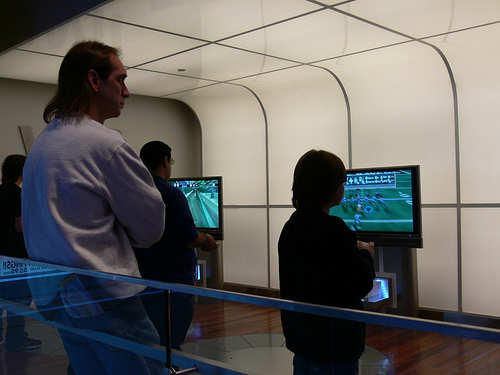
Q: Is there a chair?
A: No, there are no chairs.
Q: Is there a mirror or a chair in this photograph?
A: No, there are no chairs or mirrors.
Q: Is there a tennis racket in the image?
A: No, there are no rackets.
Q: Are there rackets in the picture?
A: No, there are no rackets.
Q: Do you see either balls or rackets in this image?
A: No, there are no rackets or balls.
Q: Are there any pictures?
A: No, there are no pictures.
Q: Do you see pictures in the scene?
A: No, there are no pictures.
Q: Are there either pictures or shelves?
A: No, there are no pictures or shelves.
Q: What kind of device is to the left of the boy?
A: The device is a screen.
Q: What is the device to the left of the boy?
A: The device is a screen.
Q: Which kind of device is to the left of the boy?
A: The device is a screen.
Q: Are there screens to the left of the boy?
A: Yes, there is a screen to the left of the boy.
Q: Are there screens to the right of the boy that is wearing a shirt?
A: No, the screen is to the left of the boy.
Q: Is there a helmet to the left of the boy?
A: No, there is a screen to the left of the boy.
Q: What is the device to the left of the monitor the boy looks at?
A: The device is a screen.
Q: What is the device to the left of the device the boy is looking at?
A: The device is a screen.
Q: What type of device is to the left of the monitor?
A: The device is a screen.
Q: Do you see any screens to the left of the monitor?
A: Yes, there is a screen to the left of the monitor.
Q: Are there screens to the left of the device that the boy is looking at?
A: Yes, there is a screen to the left of the monitor.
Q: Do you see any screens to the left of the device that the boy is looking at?
A: Yes, there is a screen to the left of the monitor.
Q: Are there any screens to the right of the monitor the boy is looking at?
A: No, the screen is to the left of the monitor.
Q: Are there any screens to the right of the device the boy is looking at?
A: No, the screen is to the left of the monitor.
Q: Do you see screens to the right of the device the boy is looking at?
A: No, the screen is to the left of the monitor.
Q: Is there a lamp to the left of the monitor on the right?
A: No, there is a screen to the left of the monitor.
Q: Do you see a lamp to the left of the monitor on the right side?
A: No, there is a screen to the left of the monitor.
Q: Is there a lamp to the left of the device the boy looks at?
A: No, there is a screen to the left of the monitor.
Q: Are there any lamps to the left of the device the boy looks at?
A: No, there is a screen to the left of the monitor.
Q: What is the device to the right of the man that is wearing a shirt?
A: The device is a screen.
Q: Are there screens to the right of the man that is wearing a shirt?
A: Yes, there is a screen to the right of the man.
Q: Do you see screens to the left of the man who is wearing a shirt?
A: No, the screen is to the right of the man.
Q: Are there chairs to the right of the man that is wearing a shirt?
A: No, there is a screen to the right of the man.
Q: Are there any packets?
A: No, there are no packets.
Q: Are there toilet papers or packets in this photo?
A: No, there are no packets or toilet papers.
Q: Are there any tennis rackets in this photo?
A: No, there are no tennis rackets.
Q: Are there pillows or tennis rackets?
A: No, there are no tennis rackets or pillows.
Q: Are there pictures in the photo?
A: No, there are no pictures.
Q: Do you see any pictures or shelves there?
A: No, there are no pictures or shelves.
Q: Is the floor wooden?
A: Yes, the floor is wooden.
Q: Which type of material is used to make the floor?
A: The floor is made of wood.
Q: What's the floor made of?
A: The floor is made of wood.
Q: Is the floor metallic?
A: No, the floor is wooden.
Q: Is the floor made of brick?
A: No, the floor is made of wood.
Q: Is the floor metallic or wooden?
A: The floor is wooden.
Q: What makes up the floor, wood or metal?
A: The floor is made of wood.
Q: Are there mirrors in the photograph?
A: No, there are no mirrors.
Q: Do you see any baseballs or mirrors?
A: No, there are no mirrors or baseballs.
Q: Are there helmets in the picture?
A: No, there are no helmets.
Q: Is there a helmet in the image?
A: No, there are no helmets.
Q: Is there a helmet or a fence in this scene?
A: No, there are no helmets or fences.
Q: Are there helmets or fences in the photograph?
A: No, there are no helmets or fences.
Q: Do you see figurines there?
A: No, there are no figurines.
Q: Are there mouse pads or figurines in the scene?
A: No, there are no figurines or mouse pads.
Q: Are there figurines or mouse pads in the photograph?
A: No, there are no figurines or mouse pads.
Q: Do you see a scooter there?
A: No, there are no scooters.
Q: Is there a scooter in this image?
A: No, there are no scooters.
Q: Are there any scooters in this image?
A: No, there are no scooters.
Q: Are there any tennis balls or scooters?
A: No, there are no scooters or tennis balls.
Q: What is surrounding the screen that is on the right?
A: The frame is surrounding the screen.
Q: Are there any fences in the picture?
A: No, there are no fences.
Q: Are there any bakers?
A: No, there are no bakers.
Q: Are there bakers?
A: No, there are no bakers.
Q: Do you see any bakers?
A: No, there are no bakers.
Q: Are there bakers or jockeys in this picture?
A: No, there are no bakers or jockeys.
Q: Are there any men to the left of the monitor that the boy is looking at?
A: Yes, there is a man to the left of the monitor.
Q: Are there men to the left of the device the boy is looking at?
A: Yes, there is a man to the left of the monitor.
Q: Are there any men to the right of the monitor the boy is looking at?
A: No, the man is to the left of the monitor.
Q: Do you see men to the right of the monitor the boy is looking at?
A: No, the man is to the left of the monitor.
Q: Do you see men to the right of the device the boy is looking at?
A: No, the man is to the left of the monitor.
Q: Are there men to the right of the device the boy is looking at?
A: No, the man is to the left of the monitor.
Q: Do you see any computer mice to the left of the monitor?
A: No, there is a man to the left of the monitor.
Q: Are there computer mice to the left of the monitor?
A: No, there is a man to the left of the monitor.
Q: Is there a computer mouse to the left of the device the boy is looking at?
A: No, there is a man to the left of the monitor.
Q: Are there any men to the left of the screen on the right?
A: Yes, there is a man to the left of the screen.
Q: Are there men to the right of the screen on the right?
A: No, the man is to the left of the screen.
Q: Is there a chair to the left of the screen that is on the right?
A: No, there is a man to the left of the screen.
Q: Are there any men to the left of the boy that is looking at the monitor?
A: Yes, there is a man to the left of the boy.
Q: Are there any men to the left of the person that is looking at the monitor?
A: Yes, there is a man to the left of the boy.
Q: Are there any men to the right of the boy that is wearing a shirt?
A: No, the man is to the left of the boy.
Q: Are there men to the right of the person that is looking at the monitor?
A: No, the man is to the left of the boy.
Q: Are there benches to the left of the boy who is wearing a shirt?
A: No, there is a man to the left of the boy.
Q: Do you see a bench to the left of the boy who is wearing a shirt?
A: No, there is a man to the left of the boy.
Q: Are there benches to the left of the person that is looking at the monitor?
A: No, there is a man to the left of the boy.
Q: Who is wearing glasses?
A: The man is wearing glasses.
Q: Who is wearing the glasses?
A: The man is wearing glasses.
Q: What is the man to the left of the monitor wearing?
A: The man is wearing glasses.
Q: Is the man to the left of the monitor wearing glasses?
A: Yes, the man is wearing glasses.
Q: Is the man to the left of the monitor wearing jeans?
A: No, the man is wearing glasses.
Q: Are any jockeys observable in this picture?
A: No, there are no jockeys.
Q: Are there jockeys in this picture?
A: No, there are no jockeys.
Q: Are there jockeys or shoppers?
A: No, there are no jockeys or shoppers.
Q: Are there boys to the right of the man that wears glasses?
A: Yes, there is a boy to the right of the man.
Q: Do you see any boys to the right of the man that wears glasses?
A: Yes, there is a boy to the right of the man.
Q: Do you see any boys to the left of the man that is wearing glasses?
A: No, the boy is to the right of the man.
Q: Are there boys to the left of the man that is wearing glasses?
A: No, the boy is to the right of the man.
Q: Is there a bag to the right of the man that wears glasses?
A: No, there is a boy to the right of the man.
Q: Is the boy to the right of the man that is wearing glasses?
A: Yes, the boy is to the right of the man.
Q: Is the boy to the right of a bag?
A: No, the boy is to the right of the man.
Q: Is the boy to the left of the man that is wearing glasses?
A: No, the boy is to the right of the man.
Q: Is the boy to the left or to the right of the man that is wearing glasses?
A: The boy is to the right of the man.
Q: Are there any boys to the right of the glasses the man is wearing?
A: Yes, there is a boy to the right of the glasses.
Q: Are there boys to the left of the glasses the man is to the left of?
A: No, the boy is to the right of the glasses.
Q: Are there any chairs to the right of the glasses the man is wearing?
A: No, there is a boy to the right of the glasses.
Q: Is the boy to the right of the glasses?
A: Yes, the boy is to the right of the glasses.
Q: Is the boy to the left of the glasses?
A: No, the boy is to the right of the glasses.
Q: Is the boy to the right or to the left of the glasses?
A: The boy is to the right of the glasses.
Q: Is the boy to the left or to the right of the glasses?
A: The boy is to the right of the glasses.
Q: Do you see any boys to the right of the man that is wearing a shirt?
A: Yes, there is a boy to the right of the man.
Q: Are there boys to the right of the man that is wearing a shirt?
A: Yes, there is a boy to the right of the man.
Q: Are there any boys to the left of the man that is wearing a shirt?
A: No, the boy is to the right of the man.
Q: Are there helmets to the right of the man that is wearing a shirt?
A: No, there is a boy to the right of the man.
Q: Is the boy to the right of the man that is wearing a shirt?
A: Yes, the boy is to the right of the man.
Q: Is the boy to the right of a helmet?
A: No, the boy is to the right of the man.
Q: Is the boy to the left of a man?
A: No, the boy is to the right of a man.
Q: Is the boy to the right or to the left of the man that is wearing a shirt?
A: The boy is to the right of the man.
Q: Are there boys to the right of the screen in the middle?
A: Yes, there is a boy to the right of the screen.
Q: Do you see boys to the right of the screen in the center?
A: Yes, there is a boy to the right of the screen.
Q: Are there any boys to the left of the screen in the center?
A: No, the boy is to the right of the screen.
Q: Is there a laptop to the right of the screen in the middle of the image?
A: No, there is a boy to the right of the screen.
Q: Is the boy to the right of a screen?
A: Yes, the boy is to the right of a screen.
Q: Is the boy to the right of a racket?
A: No, the boy is to the right of a screen.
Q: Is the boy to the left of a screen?
A: No, the boy is to the right of a screen.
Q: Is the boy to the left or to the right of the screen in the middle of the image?
A: The boy is to the right of the screen.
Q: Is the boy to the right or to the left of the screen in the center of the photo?
A: The boy is to the right of the screen.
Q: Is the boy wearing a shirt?
A: Yes, the boy is wearing a shirt.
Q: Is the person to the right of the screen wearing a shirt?
A: Yes, the boy is wearing a shirt.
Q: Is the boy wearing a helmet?
A: No, the boy is wearing a shirt.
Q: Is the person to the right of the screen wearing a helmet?
A: No, the boy is wearing a shirt.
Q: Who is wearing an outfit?
A: The boy is wearing an outfit.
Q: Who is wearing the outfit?
A: The boy is wearing an outfit.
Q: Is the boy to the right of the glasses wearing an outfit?
A: Yes, the boy is wearing an outfit.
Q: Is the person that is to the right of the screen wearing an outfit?
A: Yes, the boy is wearing an outfit.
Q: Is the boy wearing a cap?
A: No, the boy is wearing an outfit.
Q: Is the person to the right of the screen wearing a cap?
A: No, the boy is wearing an outfit.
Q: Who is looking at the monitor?
A: The boy is looking at the monitor.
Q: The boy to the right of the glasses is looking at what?
A: The boy is looking at the monitor.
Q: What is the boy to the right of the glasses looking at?
A: The boy is looking at the monitor.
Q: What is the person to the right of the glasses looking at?
A: The boy is looking at the monitor.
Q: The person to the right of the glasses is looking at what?
A: The boy is looking at the monitor.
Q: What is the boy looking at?
A: The boy is looking at the monitor.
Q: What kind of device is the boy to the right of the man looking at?
A: The boy is looking at the monitor.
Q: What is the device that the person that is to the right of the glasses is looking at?
A: The device is a monitor.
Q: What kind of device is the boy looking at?
A: The boy is looking at the monitor.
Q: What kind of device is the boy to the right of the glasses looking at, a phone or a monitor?
A: The boy is looking at a monitor.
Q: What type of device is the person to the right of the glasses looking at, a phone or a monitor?
A: The boy is looking at a monitor.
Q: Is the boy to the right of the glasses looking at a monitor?
A: Yes, the boy is looking at a monitor.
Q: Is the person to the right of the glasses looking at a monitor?
A: Yes, the boy is looking at a monitor.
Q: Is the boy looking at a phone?
A: No, the boy is looking at a monitor.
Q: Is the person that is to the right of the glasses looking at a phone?
A: No, the boy is looking at a monitor.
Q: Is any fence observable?
A: No, there are no fences.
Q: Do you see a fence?
A: No, there are no fences.